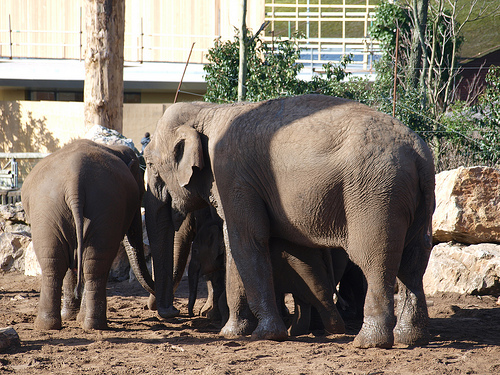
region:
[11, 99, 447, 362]
elephants standing on the dirt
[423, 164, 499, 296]
two boulders stacked on top of each other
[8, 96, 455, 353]
small elephant standing next to a bigger one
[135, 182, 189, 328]
long trunk hanging down to the ground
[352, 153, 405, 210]
lines on the skin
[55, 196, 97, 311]
thin, long, gray tail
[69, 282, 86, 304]
hair at the end of the tail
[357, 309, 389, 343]
white marks on the foot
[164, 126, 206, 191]
big floppy ear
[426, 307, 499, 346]
shadow on the ground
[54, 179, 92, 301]
Elephant's brown tail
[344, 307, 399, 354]
Back left foot of adult elephant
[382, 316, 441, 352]
Back right foot of elephant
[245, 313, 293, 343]
Front left foot of elephant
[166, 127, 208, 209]
Left ear of elephant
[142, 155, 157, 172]
Left eye of elephant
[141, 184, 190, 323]
Brown trunk of adult elephant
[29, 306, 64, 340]
Back left foot of elephant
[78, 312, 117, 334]
Back right foot of elephant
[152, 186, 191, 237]
Mouth of adult elephant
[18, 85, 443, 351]
Standing elephants.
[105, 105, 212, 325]
Elephants with their trunks down.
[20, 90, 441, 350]
Grey elephants.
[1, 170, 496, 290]
The elephants' space is fenced with stacked rocks.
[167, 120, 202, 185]
Elephant's big ear.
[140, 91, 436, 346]
The elephant is huge.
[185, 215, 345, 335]
A baby elephant is hiding under an adult one.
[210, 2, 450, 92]
Trees behind the elephants.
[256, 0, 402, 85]
Tall building on the background.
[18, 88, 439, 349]
Elephants standing on brown dirt ground.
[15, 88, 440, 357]
small elephant next to a bigger elephant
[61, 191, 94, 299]
skinny gray tail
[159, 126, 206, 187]
large gray ear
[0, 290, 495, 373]
brown dirt on the ground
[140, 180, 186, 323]
trunk hanging down towards the ground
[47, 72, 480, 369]
the elephants are gray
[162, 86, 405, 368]
the skin is wrinkled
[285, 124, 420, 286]
the skin is wrinkled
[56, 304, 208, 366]
the ground is muddy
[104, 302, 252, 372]
the ground is muddy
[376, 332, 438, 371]
the ground is muddy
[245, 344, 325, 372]
the ground is muddy